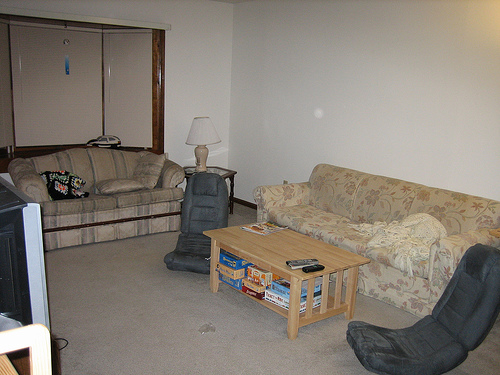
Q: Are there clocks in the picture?
A: No, there are no clocks.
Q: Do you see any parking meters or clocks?
A: No, there are no clocks or parking meters.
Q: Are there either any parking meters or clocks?
A: No, there are no clocks or parking meters.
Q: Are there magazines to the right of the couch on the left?
A: Yes, there is a magazine to the right of the couch.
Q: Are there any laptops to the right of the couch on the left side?
A: No, there is a magazine to the right of the couch.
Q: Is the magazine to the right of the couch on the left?
A: Yes, the magazine is to the right of the couch.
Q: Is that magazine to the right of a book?
A: No, the magazine is to the right of the couch.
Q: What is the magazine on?
A: The magazine is on the table.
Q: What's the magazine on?
A: The magazine is on the table.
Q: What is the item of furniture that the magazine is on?
A: The piece of furniture is a table.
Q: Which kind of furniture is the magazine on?
A: The magazine is on the table.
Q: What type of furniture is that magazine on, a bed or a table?
A: The magazine is on a table.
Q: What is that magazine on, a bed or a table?
A: The magazine is on a table.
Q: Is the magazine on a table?
A: Yes, the magazine is on a table.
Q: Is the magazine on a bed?
A: No, the magazine is on a table.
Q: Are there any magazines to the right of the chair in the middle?
A: Yes, there is a magazine to the right of the chair.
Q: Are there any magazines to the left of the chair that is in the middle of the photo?
A: No, the magazine is to the right of the chair.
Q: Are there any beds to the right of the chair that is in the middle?
A: No, there is a magazine to the right of the chair.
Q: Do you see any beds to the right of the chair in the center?
A: No, there is a magazine to the right of the chair.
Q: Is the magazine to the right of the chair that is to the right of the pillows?
A: Yes, the magazine is to the right of the chair.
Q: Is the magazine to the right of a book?
A: No, the magazine is to the right of the chair.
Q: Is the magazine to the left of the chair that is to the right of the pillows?
A: No, the magazine is to the right of the chair.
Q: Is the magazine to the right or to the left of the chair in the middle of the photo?
A: The magazine is to the right of the chair.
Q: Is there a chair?
A: Yes, there is a chair.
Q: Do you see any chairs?
A: Yes, there is a chair.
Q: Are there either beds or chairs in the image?
A: Yes, there is a chair.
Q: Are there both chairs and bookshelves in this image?
A: No, there is a chair but no bookshelves.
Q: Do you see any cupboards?
A: No, there are no cupboards.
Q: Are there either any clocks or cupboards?
A: No, there are no cupboards or clocks.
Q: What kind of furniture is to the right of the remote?
A: The piece of furniture is a chair.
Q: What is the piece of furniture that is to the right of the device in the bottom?
A: The piece of furniture is a chair.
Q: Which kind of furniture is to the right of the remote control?
A: The piece of furniture is a chair.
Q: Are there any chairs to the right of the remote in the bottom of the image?
A: Yes, there is a chair to the right of the remote.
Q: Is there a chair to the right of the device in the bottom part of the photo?
A: Yes, there is a chair to the right of the remote.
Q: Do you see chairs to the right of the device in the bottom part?
A: Yes, there is a chair to the right of the remote.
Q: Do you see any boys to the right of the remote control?
A: No, there is a chair to the right of the remote control.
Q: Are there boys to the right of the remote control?
A: No, there is a chair to the right of the remote control.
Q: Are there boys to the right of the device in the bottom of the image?
A: No, there is a chair to the right of the remote control.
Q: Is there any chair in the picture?
A: Yes, there is a chair.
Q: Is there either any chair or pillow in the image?
A: Yes, there is a chair.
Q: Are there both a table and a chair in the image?
A: Yes, there are both a chair and a table.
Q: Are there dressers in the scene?
A: No, there are no dressers.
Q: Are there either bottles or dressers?
A: No, there are no dressers or bottles.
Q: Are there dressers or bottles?
A: No, there are no dressers or bottles.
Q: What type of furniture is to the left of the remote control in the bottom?
A: The piece of furniture is a chair.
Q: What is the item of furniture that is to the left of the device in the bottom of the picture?
A: The piece of furniture is a chair.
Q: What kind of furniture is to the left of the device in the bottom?
A: The piece of furniture is a chair.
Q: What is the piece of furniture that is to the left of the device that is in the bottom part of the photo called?
A: The piece of furniture is a chair.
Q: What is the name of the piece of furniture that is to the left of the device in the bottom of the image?
A: The piece of furniture is a chair.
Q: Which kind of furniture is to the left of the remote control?
A: The piece of furniture is a chair.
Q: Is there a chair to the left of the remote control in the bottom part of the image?
A: Yes, there is a chair to the left of the remote control.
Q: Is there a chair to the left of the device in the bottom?
A: Yes, there is a chair to the left of the remote control.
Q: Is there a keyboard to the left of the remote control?
A: No, there is a chair to the left of the remote control.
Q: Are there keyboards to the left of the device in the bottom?
A: No, there is a chair to the left of the remote control.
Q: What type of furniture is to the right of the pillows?
A: The piece of furniture is a chair.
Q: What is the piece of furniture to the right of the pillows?
A: The piece of furniture is a chair.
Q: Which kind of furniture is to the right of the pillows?
A: The piece of furniture is a chair.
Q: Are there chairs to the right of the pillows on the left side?
A: Yes, there is a chair to the right of the pillows.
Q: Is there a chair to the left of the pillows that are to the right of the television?
A: No, the chair is to the right of the pillows.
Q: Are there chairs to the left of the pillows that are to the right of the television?
A: No, the chair is to the right of the pillows.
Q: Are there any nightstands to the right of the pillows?
A: No, there is a chair to the right of the pillows.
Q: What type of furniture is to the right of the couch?
A: The piece of furniture is a chair.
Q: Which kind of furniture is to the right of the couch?
A: The piece of furniture is a chair.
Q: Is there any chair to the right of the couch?
A: Yes, there is a chair to the right of the couch.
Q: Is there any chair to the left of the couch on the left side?
A: No, the chair is to the right of the couch.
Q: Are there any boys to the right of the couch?
A: No, there is a chair to the right of the couch.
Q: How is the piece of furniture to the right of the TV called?
A: The piece of furniture is a chair.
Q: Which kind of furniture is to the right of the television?
A: The piece of furniture is a chair.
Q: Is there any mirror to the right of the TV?
A: No, there is a chair to the right of the TV.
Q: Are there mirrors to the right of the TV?
A: No, there is a chair to the right of the TV.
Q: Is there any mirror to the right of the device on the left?
A: No, there is a chair to the right of the TV.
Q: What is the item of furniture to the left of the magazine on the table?
A: The piece of furniture is a chair.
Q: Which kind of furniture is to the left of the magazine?
A: The piece of furniture is a chair.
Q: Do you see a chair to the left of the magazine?
A: Yes, there is a chair to the left of the magazine.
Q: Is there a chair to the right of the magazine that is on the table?
A: No, the chair is to the left of the magazine.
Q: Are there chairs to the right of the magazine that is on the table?
A: No, the chair is to the left of the magazine.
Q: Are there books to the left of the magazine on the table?
A: No, there is a chair to the left of the magazine.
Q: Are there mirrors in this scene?
A: No, there are no mirrors.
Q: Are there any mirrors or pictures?
A: No, there are no mirrors or pictures.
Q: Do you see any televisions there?
A: Yes, there is a television.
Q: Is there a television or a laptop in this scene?
A: Yes, there is a television.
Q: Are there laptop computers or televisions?
A: Yes, there is a television.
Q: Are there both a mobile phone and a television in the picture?
A: No, there is a television but no cell phones.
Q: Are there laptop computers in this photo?
A: No, there are no laptop computers.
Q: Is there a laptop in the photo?
A: No, there are no laptops.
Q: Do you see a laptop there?
A: No, there are no laptops.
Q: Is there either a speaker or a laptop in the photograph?
A: No, there are no laptops or speakers.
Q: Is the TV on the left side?
A: Yes, the TV is on the left of the image.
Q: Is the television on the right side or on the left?
A: The television is on the left of the image.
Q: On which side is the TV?
A: The TV is on the left of the image.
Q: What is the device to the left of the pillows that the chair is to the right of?
A: The device is a television.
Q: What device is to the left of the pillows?
A: The device is a television.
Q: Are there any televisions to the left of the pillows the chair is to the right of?
A: Yes, there is a television to the left of the pillows.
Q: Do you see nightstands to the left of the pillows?
A: No, there is a television to the left of the pillows.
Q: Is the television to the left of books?
A: No, the television is to the left of the pillows.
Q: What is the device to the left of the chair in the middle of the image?
A: The device is a television.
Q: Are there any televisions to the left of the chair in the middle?
A: Yes, there is a television to the left of the chair.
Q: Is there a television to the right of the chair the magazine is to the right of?
A: No, the television is to the left of the chair.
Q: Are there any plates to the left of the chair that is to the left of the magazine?
A: No, there is a television to the left of the chair.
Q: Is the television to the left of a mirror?
A: No, the television is to the left of a chair.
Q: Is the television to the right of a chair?
A: No, the television is to the left of a chair.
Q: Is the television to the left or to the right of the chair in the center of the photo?
A: The television is to the left of the chair.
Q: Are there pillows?
A: Yes, there are pillows.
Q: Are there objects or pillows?
A: Yes, there are pillows.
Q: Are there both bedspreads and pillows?
A: No, there are pillows but no bedspreads.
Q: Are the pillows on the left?
A: Yes, the pillows are on the left of the image.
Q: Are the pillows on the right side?
A: No, the pillows are on the left of the image.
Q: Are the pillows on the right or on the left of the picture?
A: The pillows are on the left of the image.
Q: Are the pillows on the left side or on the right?
A: The pillows are on the left of the image.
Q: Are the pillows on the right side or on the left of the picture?
A: The pillows are on the left of the image.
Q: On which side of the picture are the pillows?
A: The pillows are on the left of the image.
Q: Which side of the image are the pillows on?
A: The pillows are on the left of the image.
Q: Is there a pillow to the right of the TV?
A: Yes, there are pillows to the right of the TV.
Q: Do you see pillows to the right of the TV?
A: Yes, there are pillows to the right of the TV.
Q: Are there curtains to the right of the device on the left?
A: No, there are pillows to the right of the television.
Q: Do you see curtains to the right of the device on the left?
A: No, there are pillows to the right of the television.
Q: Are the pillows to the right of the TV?
A: Yes, the pillows are to the right of the TV.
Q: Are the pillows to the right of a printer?
A: No, the pillows are to the right of the TV.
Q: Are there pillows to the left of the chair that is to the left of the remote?
A: Yes, there are pillows to the left of the chair.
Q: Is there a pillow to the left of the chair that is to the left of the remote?
A: Yes, there are pillows to the left of the chair.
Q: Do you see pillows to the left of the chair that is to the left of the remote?
A: Yes, there are pillows to the left of the chair.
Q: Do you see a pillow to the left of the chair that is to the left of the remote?
A: Yes, there are pillows to the left of the chair.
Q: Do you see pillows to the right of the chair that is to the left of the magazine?
A: No, the pillows are to the left of the chair.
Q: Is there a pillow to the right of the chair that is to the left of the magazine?
A: No, the pillows are to the left of the chair.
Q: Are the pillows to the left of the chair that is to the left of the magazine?
A: Yes, the pillows are to the left of the chair.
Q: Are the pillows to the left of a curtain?
A: No, the pillows are to the left of the chair.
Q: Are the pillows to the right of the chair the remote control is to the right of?
A: No, the pillows are to the left of the chair.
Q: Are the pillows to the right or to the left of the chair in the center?
A: The pillows are to the left of the chair.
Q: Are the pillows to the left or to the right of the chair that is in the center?
A: The pillows are to the left of the chair.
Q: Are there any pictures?
A: No, there are no pictures.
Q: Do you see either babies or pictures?
A: No, there are no pictures or babies.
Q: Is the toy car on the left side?
A: Yes, the toy car is on the left of the image.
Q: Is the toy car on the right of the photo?
A: No, the toy car is on the left of the image.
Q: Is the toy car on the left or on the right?
A: The toy car is on the left of the image.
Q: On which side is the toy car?
A: The toy car is on the left of the image.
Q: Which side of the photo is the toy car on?
A: The toy car is on the left of the image.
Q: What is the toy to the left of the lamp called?
A: The toy is a toy car.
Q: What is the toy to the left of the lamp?
A: The toy is a toy car.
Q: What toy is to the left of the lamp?
A: The toy is a toy car.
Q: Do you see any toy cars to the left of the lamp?
A: Yes, there is a toy car to the left of the lamp.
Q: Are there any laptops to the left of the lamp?
A: No, there is a toy car to the left of the lamp.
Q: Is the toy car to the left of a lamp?
A: Yes, the toy car is to the left of a lamp.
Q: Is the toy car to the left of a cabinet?
A: No, the toy car is to the left of a lamp.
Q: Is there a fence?
A: No, there are no fences.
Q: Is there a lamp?
A: Yes, there is a lamp.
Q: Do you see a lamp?
A: Yes, there is a lamp.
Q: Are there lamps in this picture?
A: Yes, there is a lamp.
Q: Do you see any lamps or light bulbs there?
A: Yes, there is a lamp.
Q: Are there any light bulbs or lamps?
A: Yes, there is a lamp.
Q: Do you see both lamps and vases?
A: No, there is a lamp but no vases.